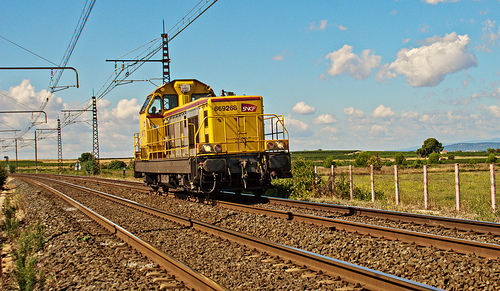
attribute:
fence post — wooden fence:
[344, 163, 359, 204]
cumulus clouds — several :
[318, 25, 485, 112]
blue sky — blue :
[246, 13, 353, 90]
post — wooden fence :
[90, 94, 101, 165]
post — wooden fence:
[356, 157, 395, 199]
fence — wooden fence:
[66, 155, 498, 222]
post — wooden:
[451, 160, 466, 213]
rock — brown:
[14, 173, 499, 289]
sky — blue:
[1, 1, 498, 158]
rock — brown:
[194, 248, 286, 289]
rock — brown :
[55, 230, 67, 239]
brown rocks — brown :
[94, 201, 202, 261]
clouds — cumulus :
[389, 31, 475, 83]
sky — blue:
[307, 15, 495, 121]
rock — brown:
[190, 247, 255, 269]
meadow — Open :
[317, 162, 499, 213]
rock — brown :
[55, 201, 112, 229]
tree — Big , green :
[421, 126, 452, 165]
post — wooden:
[450, 154, 467, 212]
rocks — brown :
[157, 227, 206, 252]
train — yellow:
[134, 78, 291, 208]